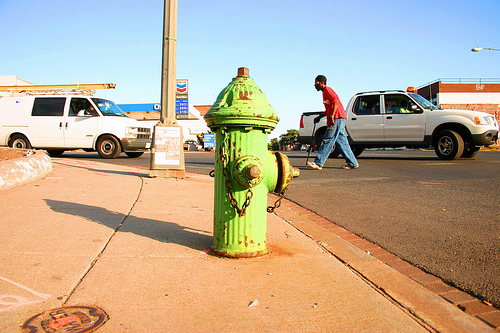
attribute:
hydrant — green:
[202, 65, 299, 258]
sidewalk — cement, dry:
[0, 159, 499, 331]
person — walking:
[308, 72, 362, 170]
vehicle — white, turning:
[294, 88, 498, 161]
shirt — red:
[319, 84, 347, 120]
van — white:
[0, 81, 151, 158]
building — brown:
[412, 77, 500, 137]